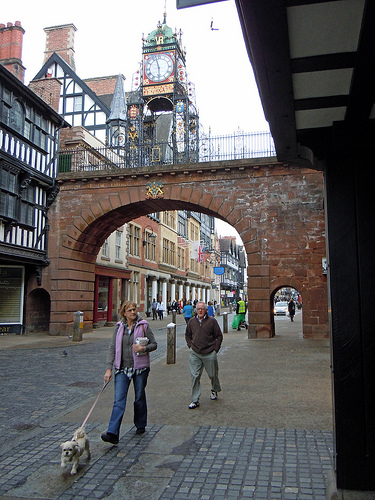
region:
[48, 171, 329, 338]
a red brick wall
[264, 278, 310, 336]
a small arched doorway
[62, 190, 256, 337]
a large arched doorway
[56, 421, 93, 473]
a small dog on a leash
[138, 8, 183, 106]
a clock tower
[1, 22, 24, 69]
a red brick chimney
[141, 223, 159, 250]
a light hanging between two windows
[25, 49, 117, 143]
a white and black peaked building with a peaked roof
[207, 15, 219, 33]
a bird in the sky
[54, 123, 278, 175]
a railing above a red brick wall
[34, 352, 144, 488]
Dog on a leash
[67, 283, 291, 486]
Man and woman walking down the street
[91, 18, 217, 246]
Big clock tower in a city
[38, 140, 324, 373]
Bridge over a street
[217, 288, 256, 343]
guy holding a green trash bag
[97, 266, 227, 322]
stores on a city walk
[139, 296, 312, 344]
People walking down the street shopping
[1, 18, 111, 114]
Chimnys on tops of buildings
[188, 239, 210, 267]
British flag over store fronts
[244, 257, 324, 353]
small archway by side walk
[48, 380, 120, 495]
the dog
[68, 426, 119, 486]
the dog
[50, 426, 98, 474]
small white dog being walked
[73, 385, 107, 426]
a pink dog leash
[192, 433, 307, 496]
small grey bricks on path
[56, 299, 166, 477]
woman walking small dog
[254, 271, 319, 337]
entrance way in stone arch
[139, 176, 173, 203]
design on stone arch way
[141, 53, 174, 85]
large clock on tower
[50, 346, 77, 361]
pigeon standing on path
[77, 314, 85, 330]
sign on stone pole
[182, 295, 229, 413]
man in brown coat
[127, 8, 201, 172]
an ornate clock tower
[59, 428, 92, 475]
a small dog taking a walk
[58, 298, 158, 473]
a woman walking a small dog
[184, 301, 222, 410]
an older man in a brown jacket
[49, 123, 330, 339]
a stone arch over the cobblestone street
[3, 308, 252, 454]
a cobblestone street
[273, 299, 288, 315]
a small white car in the background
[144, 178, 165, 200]
a coat of arms on the arch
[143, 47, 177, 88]
a red and white clock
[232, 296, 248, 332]
a worker carrying a green plastic bag